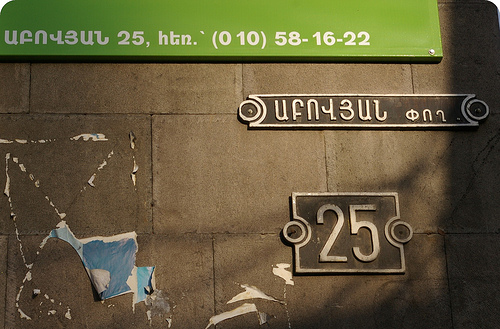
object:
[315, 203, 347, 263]
number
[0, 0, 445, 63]
sign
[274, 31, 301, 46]
58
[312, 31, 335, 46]
16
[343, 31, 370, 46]
22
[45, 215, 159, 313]
paper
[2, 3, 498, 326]
wall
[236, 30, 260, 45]
0 10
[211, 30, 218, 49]
parenthesis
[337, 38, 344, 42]
-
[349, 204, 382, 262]
5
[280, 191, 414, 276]
sign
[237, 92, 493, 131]
sign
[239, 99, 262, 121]
circle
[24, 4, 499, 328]
shadow